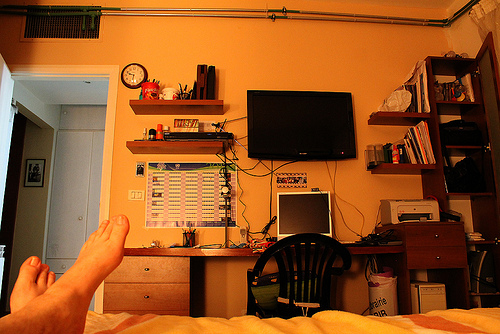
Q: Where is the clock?
A: On wall.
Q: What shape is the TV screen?
A: Rectangular.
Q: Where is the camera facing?
A: Towards wall.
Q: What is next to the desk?
A: Chair.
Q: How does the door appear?
A: Open.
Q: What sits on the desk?
A: Computer monitor.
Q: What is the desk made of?
A: Wood.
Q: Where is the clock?
A: Near upper right hand corner of the door.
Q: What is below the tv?
A: Desk.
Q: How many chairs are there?
A: One.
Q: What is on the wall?
A: A tv.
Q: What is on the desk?
A: A computer monitor.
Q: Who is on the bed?
A: A person.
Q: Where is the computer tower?
A: Under the desk.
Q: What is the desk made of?
A: Wood.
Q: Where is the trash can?
A: Under the desk.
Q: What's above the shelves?
A: A clock.